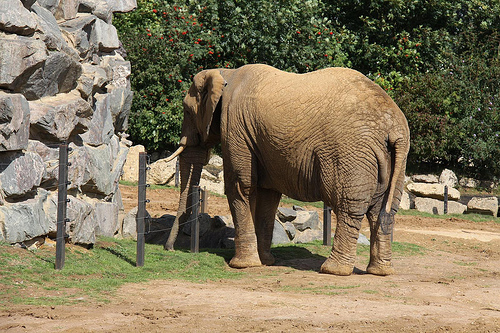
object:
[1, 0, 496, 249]
rock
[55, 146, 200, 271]
post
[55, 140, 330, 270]
fence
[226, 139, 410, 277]
leg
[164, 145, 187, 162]
tusk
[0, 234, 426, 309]
grass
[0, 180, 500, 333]
ground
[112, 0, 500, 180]
tree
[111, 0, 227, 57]
bloom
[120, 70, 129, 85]
bird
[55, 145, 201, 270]
hooks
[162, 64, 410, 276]
elephant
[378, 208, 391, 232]
hair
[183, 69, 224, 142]
face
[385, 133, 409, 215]
tail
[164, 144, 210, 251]
trunk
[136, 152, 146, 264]
pole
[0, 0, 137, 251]
wall